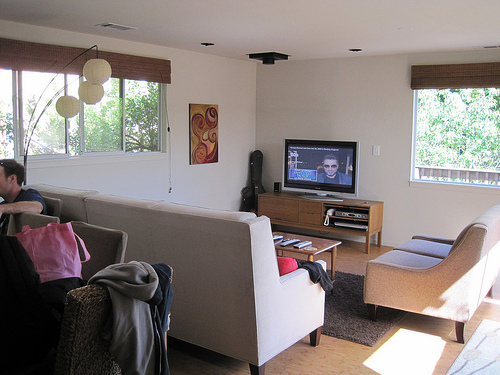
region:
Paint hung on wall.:
[184, 93, 226, 168]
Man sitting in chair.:
[0, 160, 50, 219]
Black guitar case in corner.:
[240, 136, 264, 217]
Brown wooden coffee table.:
[272, 228, 343, 285]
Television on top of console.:
[280, 135, 359, 204]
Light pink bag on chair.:
[15, 219, 102, 277]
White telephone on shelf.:
[320, 206, 335, 224]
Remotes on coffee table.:
[273, 227, 311, 251]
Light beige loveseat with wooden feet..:
[361, 206, 495, 346]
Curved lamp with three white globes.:
[20, 42, 110, 177]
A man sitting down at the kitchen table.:
[0, 160, 52, 254]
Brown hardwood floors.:
[163, 227, 496, 374]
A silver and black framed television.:
[280, 137, 360, 199]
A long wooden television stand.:
[257, 185, 386, 255]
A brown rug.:
[316, 265, 416, 347]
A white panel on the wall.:
[371, 145, 380, 156]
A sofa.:
[27, 178, 331, 373]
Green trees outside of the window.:
[2, 77, 498, 164]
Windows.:
[0, 68, 499, 191]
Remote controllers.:
[272, 233, 312, 252]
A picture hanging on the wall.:
[187, 100, 220, 163]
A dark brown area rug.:
[309, 261, 409, 345]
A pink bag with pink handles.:
[16, 222, 90, 281]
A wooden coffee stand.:
[265, 225, 341, 286]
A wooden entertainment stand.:
[251, 190, 383, 252]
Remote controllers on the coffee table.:
[274, 232, 311, 251]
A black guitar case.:
[241, 148, 266, 214]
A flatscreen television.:
[277, 138, 359, 198]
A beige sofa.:
[29, 183, 329, 373]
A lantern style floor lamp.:
[20, 45, 110, 182]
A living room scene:
[0, 0, 498, 372]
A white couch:
[24, 181, 328, 373]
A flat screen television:
[280, 135, 362, 200]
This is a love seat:
[361, 200, 498, 342]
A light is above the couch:
[18, 42, 115, 195]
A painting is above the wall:
[186, 100, 221, 166]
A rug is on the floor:
[311, 265, 408, 348]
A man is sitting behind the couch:
[0, 154, 63, 234]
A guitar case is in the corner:
[236, 148, 267, 213]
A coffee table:
[269, 227, 343, 281]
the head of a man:
[0, 153, 30, 203]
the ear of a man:
[6, 170, 18, 185]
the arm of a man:
[0, 185, 50, 219]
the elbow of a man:
[32, 200, 49, 217]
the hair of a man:
[1, 157, 29, 188]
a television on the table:
[278, 135, 363, 202]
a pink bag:
[10, 220, 100, 287]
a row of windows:
[0, 53, 176, 166]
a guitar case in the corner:
[233, 142, 273, 216]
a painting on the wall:
[183, 99, 227, 170]